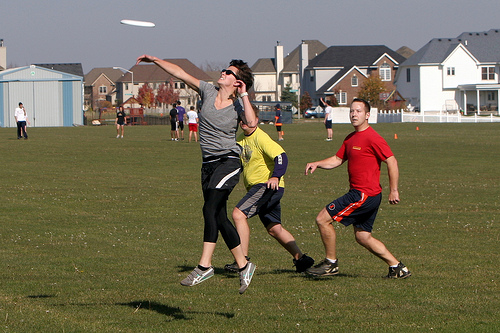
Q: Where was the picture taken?
A: It was taken at the field.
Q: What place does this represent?
A: It represents the field.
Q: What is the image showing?
A: It is showing a field.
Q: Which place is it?
A: It is a field.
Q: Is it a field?
A: Yes, it is a field.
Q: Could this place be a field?
A: Yes, it is a field.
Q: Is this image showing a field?
A: Yes, it is showing a field.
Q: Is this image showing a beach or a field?
A: It is showing a field.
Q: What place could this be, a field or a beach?
A: It is a field.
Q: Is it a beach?
A: No, it is a field.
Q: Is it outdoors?
A: Yes, it is outdoors.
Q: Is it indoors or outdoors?
A: It is outdoors.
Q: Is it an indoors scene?
A: No, it is outdoors.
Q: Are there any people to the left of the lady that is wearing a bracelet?
A: Yes, there is a person to the left of the lady.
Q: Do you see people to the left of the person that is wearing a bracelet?
A: Yes, there is a person to the left of the lady.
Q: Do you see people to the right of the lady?
A: No, the person is to the left of the lady.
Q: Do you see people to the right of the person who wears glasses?
A: No, the person is to the left of the lady.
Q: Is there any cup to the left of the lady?
A: No, there is a person to the left of the lady.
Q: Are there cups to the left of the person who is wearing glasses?
A: No, there is a person to the left of the lady.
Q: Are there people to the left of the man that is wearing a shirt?
A: Yes, there is a person to the left of the man.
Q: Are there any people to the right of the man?
A: No, the person is to the left of the man.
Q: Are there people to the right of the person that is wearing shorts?
A: No, the person is to the left of the man.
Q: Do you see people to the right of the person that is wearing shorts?
A: No, the person is to the left of the man.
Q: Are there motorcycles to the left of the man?
A: No, there is a person to the left of the man.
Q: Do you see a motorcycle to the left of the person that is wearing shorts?
A: No, there is a person to the left of the man.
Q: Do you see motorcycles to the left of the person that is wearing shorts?
A: No, there is a person to the left of the man.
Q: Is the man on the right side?
A: Yes, the man is on the right of the image.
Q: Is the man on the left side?
A: No, the man is on the right of the image.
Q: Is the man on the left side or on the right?
A: The man is on the right of the image.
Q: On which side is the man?
A: The man is on the right of the image.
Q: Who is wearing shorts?
A: The man is wearing shorts.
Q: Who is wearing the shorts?
A: The man is wearing shorts.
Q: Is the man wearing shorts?
A: Yes, the man is wearing shorts.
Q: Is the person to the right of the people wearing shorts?
A: Yes, the man is wearing shorts.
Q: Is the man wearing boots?
A: No, the man is wearing shorts.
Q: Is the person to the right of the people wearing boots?
A: No, the man is wearing shorts.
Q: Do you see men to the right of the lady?
A: Yes, there is a man to the right of the lady.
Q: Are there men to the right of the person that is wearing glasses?
A: Yes, there is a man to the right of the lady.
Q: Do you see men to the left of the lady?
A: No, the man is to the right of the lady.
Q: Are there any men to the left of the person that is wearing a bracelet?
A: No, the man is to the right of the lady.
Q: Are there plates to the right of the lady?
A: No, there is a man to the right of the lady.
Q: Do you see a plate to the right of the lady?
A: No, there is a man to the right of the lady.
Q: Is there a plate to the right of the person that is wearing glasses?
A: No, there is a man to the right of the lady.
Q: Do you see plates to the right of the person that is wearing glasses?
A: No, there is a man to the right of the lady.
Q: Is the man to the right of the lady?
A: Yes, the man is to the right of the lady.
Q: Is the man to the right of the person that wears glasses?
A: Yes, the man is to the right of the lady.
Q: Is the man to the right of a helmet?
A: No, the man is to the right of the lady.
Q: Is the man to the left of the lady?
A: No, the man is to the right of the lady.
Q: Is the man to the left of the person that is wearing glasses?
A: No, the man is to the right of the lady.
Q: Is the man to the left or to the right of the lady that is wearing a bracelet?
A: The man is to the right of the lady.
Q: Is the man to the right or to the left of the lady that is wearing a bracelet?
A: The man is to the right of the lady.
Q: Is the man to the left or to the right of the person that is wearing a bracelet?
A: The man is to the right of the lady.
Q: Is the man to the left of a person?
A: No, the man is to the right of a person.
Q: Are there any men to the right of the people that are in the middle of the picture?
A: Yes, there is a man to the right of the people.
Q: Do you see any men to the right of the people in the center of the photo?
A: Yes, there is a man to the right of the people.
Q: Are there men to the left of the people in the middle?
A: No, the man is to the right of the people.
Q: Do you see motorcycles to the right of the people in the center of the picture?
A: No, there is a man to the right of the people.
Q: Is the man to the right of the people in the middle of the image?
A: Yes, the man is to the right of the people.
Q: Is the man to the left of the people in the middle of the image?
A: No, the man is to the right of the people.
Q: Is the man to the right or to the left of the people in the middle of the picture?
A: The man is to the right of the people.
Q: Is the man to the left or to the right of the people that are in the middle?
A: The man is to the right of the people.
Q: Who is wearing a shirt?
A: The man is wearing a shirt.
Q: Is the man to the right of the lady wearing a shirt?
A: Yes, the man is wearing a shirt.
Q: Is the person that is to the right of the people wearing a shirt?
A: Yes, the man is wearing a shirt.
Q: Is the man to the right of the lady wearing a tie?
A: No, the man is wearing a shirt.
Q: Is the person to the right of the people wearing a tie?
A: No, the man is wearing a shirt.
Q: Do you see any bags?
A: No, there are no bags.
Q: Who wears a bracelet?
A: The lady wears a bracelet.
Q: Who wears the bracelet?
A: The lady wears a bracelet.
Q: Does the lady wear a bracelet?
A: Yes, the lady wears a bracelet.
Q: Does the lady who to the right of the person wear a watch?
A: No, the lady wears a bracelet.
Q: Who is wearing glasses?
A: The lady is wearing glasses.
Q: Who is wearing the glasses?
A: The lady is wearing glasses.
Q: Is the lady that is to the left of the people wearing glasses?
A: Yes, the lady is wearing glasses.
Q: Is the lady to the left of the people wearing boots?
A: No, the lady is wearing glasses.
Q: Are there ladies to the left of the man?
A: Yes, there is a lady to the left of the man.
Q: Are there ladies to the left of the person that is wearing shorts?
A: Yes, there is a lady to the left of the man.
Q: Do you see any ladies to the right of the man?
A: No, the lady is to the left of the man.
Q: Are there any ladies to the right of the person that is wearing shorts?
A: No, the lady is to the left of the man.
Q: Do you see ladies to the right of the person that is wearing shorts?
A: No, the lady is to the left of the man.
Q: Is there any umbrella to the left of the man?
A: No, there is a lady to the left of the man.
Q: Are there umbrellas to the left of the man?
A: No, there is a lady to the left of the man.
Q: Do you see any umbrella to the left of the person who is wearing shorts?
A: No, there is a lady to the left of the man.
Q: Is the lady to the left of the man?
A: Yes, the lady is to the left of the man.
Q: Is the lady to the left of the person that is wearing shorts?
A: Yes, the lady is to the left of the man.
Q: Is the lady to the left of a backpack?
A: No, the lady is to the left of the man.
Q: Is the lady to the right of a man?
A: No, the lady is to the left of a man.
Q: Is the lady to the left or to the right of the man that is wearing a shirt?
A: The lady is to the left of the man.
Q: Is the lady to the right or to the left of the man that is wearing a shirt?
A: The lady is to the left of the man.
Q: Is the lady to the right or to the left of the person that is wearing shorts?
A: The lady is to the left of the man.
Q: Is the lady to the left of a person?
A: No, the lady is to the right of a person.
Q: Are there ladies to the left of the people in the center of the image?
A: Yes, there is a lady to the left of the people.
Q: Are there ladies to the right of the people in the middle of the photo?
A: No, the lady is to the left of the people.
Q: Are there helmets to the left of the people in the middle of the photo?
A: No, there is a lady to the left of the people.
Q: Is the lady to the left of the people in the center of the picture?
A: Yes, the lady is to the left of the people.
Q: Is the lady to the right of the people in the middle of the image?
A: No, the lady is to the left of the people.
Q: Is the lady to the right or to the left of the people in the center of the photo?
A: The lady is to the left of the people.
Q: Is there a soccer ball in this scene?
A: No, there are no soccer balls.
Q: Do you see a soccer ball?
A: No, there are no soccer balls.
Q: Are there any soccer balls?
A: No, there are no soccer balls.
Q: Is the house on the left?
A: No, the house is on the right of the image.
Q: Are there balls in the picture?
A: No, there are no balls.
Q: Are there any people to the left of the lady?
A: Yes, there is a person to the left of the lady.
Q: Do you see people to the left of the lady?
A: Yes, there is a person to the left of the lady.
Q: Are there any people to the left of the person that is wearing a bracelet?
A: Yes, there is a person to the left of the lady.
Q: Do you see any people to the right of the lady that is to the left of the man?
A: No, the person is to the left of the lady.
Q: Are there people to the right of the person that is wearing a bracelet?
A: No, the person is to the left of the lady.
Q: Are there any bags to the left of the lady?
A: No, there is a person to the left of the lady.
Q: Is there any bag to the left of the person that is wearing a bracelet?
A: No, there is a person to the left of the lady.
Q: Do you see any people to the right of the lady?
A: Yes, there are people to the right of the lady.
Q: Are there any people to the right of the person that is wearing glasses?
A: Yes, there are people to the right of the lady.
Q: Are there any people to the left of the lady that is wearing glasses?
A: No, the people are to the right of the lady.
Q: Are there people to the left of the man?
A: Yes, there are people to the left of the man.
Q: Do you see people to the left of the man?
A: Yes, there are people to the left of the man.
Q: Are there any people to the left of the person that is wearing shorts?
A: Yes, there are people to the left of the man.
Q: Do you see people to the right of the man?
A: No, the people are to the left of the man.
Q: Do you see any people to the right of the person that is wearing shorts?
A: No, the people are to the left of the man.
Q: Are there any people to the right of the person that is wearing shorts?
A: No, the people are to the left of the man.